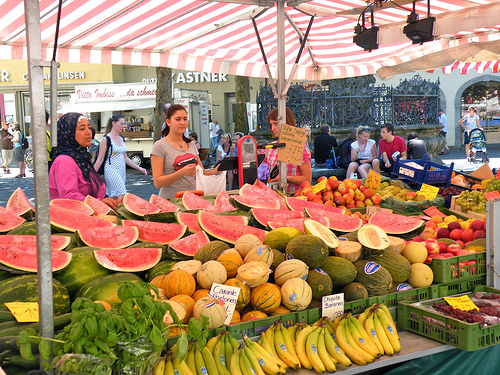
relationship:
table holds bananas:
[283, 324, 457, 374] [149, 285, 450, 363]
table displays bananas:
[283, 324, 457, 374] [149, 285, 450, 363]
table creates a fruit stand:
[404, 343, 448, 368] [5, 4, 483, 354]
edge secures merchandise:
[398, 301, 469, 352] [435, 300, 476, 319]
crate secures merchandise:
[398, 289, 498, 350] [443, 284, 483, 325]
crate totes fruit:
[394, 157, 457, 188] [410, 159, 425, 171]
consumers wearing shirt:
[149, 104, 223, 202] [147, 131, 194, 192]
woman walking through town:
[98, 109, 134, 201] [3, 40, 478, 201]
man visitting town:
[379, 122, 403, 172] [0, 0, 500, 200]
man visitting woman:
[379, 122, 403, 172] [347, 126, 377, 173]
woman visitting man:
[347, 126, 377, 173] [379, 122, 403, 172]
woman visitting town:
[347, 126, 377, 173] [0, 0, 500, 200]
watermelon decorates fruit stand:
[4, 181, 433, 275] [5, 132, 481, 353]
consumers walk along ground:
[32, 106, 319, 180] [426, 158, 463, 192]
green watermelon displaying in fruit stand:
[92, 244, 164, 268] [3, 169, 483, 358]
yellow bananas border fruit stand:
[247, 325, 345, 371] [5, 132, 481, 353]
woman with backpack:
[93, 116, 147, 194] [93, 133, 110, 173]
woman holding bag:
[146, 98, 219, 207] [187, 163, 234, 195]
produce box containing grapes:
[446, 195, 488, 220] [456, 189, 483, 211]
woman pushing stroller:
[458, 105, 480, 160] [461, 127, 493, 167]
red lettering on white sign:
[71, 86, 163, 97] [76, 83, 174, 105]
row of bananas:
[157, 297, 402, 369] [153, 296, 403, 371]